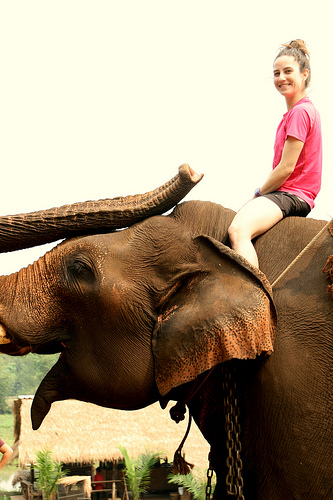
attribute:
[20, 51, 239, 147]
sky — blue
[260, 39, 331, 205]
girl — smiling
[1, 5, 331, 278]
clouds — white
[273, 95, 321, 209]
shirt — red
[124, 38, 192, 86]
sky — blue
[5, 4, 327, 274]
sky — blue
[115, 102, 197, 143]
cloud — white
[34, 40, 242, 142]
sky — blue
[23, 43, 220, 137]
clouds — white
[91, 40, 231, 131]
clouds — white